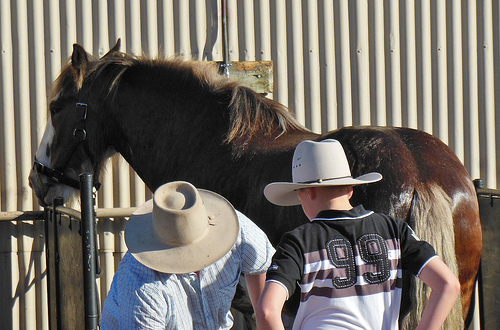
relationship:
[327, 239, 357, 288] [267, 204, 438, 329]
number on clothing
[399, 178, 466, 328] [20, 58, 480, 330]
tail on horse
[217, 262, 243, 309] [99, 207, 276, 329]
pocket on shirt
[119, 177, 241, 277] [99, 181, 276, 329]
cowboy hat on man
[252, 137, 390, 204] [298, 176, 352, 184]
hat with black felt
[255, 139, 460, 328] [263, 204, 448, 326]
boy has shirt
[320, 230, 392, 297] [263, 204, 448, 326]
number on shirt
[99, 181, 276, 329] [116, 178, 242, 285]
man has hat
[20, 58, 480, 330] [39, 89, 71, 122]
horse has eye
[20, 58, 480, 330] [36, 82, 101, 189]
horse has bridle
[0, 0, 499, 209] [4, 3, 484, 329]
metal wall in background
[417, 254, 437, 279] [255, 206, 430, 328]
stripe on shirt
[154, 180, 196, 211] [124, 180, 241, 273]
indent in cowboy hat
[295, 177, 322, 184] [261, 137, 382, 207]
black felt around hat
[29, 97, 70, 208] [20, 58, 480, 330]
face on horse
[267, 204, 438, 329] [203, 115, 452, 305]
clothing on boy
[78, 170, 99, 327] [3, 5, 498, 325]
post in pen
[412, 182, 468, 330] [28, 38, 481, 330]
tail of horse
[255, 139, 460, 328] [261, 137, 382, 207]
boy wearing a hat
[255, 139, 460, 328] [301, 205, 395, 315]
boy wearing a shirt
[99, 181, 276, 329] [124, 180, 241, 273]
man wearing a cowboy hat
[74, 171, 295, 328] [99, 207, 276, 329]
man wearing a shirt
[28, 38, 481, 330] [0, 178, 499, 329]
horse near a pen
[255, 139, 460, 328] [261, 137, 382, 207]
boy in a hat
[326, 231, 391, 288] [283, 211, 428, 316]
number on a shirt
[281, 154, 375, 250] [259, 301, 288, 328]
boy with hand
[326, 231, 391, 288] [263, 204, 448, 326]
number on shirt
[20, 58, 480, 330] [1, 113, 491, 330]
horse in pen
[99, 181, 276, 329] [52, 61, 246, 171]
man next to horse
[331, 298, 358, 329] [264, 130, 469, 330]
back of boy